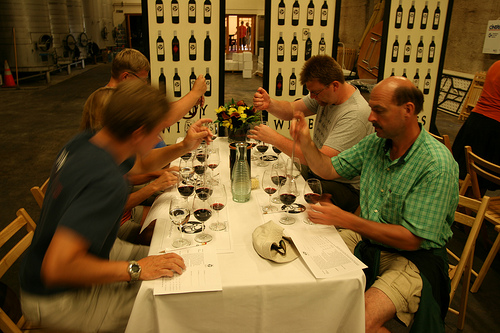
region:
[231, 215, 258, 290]
the table clothe is white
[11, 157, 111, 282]
the top is blue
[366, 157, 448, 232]
the shirt is green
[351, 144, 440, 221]
the shirt is checked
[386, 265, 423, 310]
the short is brown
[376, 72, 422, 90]
the head is balb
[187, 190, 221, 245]
the glass has red wine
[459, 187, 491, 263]
the chair is wooden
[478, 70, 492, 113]
the top is red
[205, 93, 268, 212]
Flower vase at center of table.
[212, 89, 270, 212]
Flower vase filled with flowers.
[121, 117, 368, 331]
White tablecloth covers table.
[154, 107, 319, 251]
Glasses of wine litter the table.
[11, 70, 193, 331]
First man on left wears watch.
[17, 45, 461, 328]
Five peaple seated at table.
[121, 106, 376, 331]
Table is long and rectangular.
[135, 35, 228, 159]
Wall divider has picture of wine bottles.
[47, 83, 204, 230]
Woman is writing on paper.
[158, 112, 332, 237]
Each glass has small amount of wine.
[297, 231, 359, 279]
a piece of white paper on the table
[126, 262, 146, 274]
a silver watch on mans hand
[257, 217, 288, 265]
a white ball cap sitting on the table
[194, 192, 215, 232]
a glass of wine on the table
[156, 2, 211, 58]
a picture with bottles of wine in the background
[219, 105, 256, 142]
flowers on top of the table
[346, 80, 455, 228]
man wearing green shirt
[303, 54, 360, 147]
man wearing a grey shirt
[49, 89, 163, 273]
man wearing a black shirt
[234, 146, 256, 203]
an empty vase on the table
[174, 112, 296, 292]
the table is full of drinks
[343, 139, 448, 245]
the man is wearing a green shirt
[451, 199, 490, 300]
the man is sited on a chair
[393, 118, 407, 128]
the mans color is white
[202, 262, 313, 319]
the table is placed a white clothe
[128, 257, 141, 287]
the man is wearing a wrist watch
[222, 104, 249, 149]
a flower vase is in the middle of the table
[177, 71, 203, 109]
the mans hand is raised on the air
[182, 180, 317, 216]
the glasses of wine are half full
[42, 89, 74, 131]
the floor is grey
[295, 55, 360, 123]
the man is wearing glasses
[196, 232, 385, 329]
the table cloth is white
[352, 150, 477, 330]
the man is wearing clothes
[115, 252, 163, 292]
the man has a watch on his wrist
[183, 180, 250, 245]
a drink is in the glass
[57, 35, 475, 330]
the people are in the seated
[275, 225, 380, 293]
a paper is on the table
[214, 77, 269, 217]
a flower vase is on the table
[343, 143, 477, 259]
the mans shirt is checked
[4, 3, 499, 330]
the photo was taken indoors